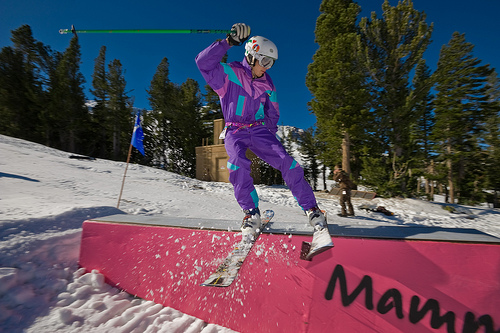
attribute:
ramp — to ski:
[77, 210, 498, 326]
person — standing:
[324, 158, 365, 219]